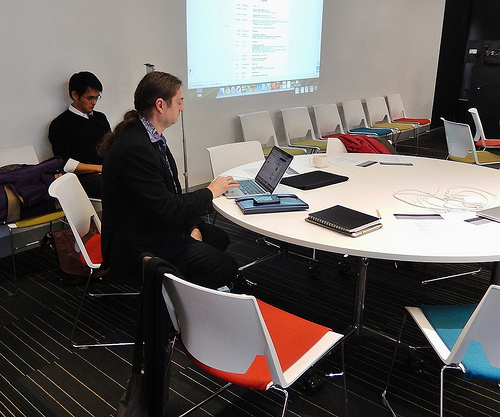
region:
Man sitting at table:
[76, 66, 241, 286]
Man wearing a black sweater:
[42, 70, 133, 204]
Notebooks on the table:
[303, 194, 385, 245]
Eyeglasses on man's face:
[79, 81, 106, 104]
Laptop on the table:
[210, 148, 303, 197]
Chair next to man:
[108, 243, 349, 415]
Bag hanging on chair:
[108, 253, 193, 414]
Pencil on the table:
[370, 201, 389, 228]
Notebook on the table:
[230, 191, 313, 217]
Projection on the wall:
[174, 39, 336, 108]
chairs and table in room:
[47, 134, 497, 376]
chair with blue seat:
[408, 285, 494, 392]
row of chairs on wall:
[221, 93, 423, 143]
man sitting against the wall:
[51, 65, 116, 200]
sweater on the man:
[46, 110, 115, 153]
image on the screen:
[170, 8, 325, 90]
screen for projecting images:
[126, 5, 446, 125]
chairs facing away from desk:
[440, 101, 499, 158]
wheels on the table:
[326, 357, 431, 377]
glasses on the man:
[76, 90, 108, 102]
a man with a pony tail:
[103, 70, 232, 295]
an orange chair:
[142, 258, 351, 415]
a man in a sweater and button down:
[38, 66, 114, 198]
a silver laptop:
[215, 145, 293, 198]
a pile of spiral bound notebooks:
[305, 201, 381, 240]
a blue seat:
[381, 278, 498, 415]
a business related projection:
[172, 0, 324, 100]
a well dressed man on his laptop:
[98, 65, 291, 333]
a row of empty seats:
[242, 88, 498, 175]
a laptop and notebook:
[221, 145, 316, 220]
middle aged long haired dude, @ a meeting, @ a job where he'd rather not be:
[79, 63, 313, 414]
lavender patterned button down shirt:
[132, 116, 185, 200]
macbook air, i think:
[215, 140, 301, 206]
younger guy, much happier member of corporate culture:
[40, 64, 125, 204]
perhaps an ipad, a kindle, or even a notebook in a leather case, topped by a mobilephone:
[235, 189, 313, 217]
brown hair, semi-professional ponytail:
[105, 66, 183, 142]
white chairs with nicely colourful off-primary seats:
[36, 85, 497, 413]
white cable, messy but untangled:
[382, 173, 497, 228]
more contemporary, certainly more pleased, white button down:
[45, 103, 111, 170]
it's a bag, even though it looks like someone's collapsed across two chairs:
[0, 151, 78, 232]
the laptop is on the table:
[198, 128, 301, 257]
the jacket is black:
[71, 113, 233, 277]